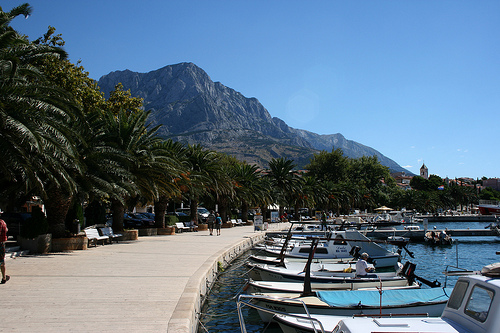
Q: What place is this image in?
A: It is at the sidewalk.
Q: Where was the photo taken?
A: It was taken at the sidewalk.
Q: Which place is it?
A: It is a sidewalk.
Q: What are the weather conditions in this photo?
A: It is clear.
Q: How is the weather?
A: It is clear.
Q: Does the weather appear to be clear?
A: Yes, it is clear.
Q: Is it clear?
A: Yes, it is clear.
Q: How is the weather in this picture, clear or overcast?
A: It is clear.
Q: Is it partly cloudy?
A: No, it is clear.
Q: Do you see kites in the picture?
A: No, there are no kites.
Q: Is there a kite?
A: No, there are no kites.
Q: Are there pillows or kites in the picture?
A: No, there are no kites or pillows.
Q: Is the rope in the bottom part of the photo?
A: Yes, the rope is in the bottom of the image.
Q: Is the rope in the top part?
A: No, the rope is in the bottom of the image.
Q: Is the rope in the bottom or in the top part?
A: The rope is in the bottom of the image.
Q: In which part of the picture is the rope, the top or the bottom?
A: The rope is in the bottom of the image.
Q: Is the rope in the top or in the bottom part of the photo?
A: The rope is in the bottom of the image.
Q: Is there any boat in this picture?
A: Yes, there is a boat.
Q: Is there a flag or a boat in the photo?
A: Yes, there is a boat.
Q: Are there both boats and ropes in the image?
A: Yes, there are both a boat and a rope.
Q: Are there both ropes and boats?
A: Yes, there are both a boat and a rope.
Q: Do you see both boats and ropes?
A: Yes, there are both a boat and a rope.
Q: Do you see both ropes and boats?
A: Yes, there are both a boat and a rope.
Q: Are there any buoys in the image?
A: No, there are no buoys.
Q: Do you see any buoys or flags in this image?
A: No, there are no buoys or flags.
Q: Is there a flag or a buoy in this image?
A: No, there are no buoys or flags.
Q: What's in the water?
A: The boat is in the water.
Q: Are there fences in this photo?
A: No, there are no fences.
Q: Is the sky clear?
A: Yes, the sky is clear.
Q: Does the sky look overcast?
A: No, the sky is clear.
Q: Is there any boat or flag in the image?
A: Yes, there is a boat.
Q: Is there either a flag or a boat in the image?
A: Yes, there is a boat.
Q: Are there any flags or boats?
A: Yes, there is a boat.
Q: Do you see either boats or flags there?
A: Yes, there is a boat.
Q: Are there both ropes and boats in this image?
A: Yes, there are both a boat and a rope.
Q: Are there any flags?
A: No, there are no flags.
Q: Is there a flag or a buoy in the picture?
A: No, there are no flags or buoys.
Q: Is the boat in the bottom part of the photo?
A: Yes, the boat is in the bottom of the image.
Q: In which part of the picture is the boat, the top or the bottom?
A: The boat is in the bottom of the image.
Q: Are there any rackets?
A: No, there are no rackets.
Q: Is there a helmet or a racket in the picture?
A: No, there are no rackets or helmets.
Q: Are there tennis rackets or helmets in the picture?
A: No, there are no tennis rackets or helmets.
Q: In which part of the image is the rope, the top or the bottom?
A: The rope is in the bottom of the image.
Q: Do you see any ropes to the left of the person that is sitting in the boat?
A: Yes, there is a rope to the left of the person.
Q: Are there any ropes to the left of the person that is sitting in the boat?
A: Yes, there is a rope to the left of the person.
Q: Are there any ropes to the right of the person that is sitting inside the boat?
A: No, the rope is to the left of the person.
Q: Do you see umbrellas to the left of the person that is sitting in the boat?
A: No, there is a rope to the left of the person.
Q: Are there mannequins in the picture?
A: No, there are no mannequins.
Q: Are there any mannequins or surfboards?
A: No, there are no mannequins or surfboards.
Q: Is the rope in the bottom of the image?
A: Yes, the rope is in the bottom of the image.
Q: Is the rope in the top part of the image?
A: No, the rope is in the bottom of the image.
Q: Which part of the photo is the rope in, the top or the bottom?
A: The rope is in the bottom of the image.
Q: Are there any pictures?
A: No, there are no pictures.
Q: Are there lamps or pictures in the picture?
A: No, there are no pictures or lamps.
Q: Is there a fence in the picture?
A: No, there are no fences.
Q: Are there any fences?
A: No, there are no fences.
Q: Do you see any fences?
A: No, there are no fences.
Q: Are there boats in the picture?
A: Yes, there is a boat.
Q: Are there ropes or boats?
A: Yes, there is a boat.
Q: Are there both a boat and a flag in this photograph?
A: No, there is a boat but no flags.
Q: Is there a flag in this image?
A: No, there are no flags.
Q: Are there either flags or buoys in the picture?
A: No, there are no flags or buoys.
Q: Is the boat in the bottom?
A: Yes, the boat is in the bottom of the image.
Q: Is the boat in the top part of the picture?
A: No, the boat is in the bottom of the image.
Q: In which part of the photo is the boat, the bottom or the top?
A: The boat is in the bottom of the image.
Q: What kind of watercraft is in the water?
A: The watercraft is a boat.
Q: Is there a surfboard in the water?
A: No, there is a boat in the water.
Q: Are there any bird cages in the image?
A: No, there are no bird cages.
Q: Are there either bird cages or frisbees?
A: No, there are no bird cages or frisbees.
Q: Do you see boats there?
A: Yes, there is a boat.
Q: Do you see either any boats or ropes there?
A: Yes, there is a boat.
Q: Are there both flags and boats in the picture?
A: No, there is a boat but no flags.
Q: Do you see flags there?
A: No, there are no flags.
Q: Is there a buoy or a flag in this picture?
A: No, there are no flags or buoys.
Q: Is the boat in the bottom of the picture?
A: Yes, the boat is in the bottom of the image.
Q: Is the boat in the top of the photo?
A: No, the boat is in the bottom of the image.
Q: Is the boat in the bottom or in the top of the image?
A: The boat is in the bottom of the image.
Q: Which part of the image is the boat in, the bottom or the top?
A: The boat is in the bottom of the image.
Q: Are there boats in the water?
A: Yes, there is a boat in the water.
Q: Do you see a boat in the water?
A: Yes, there is a boat in the water.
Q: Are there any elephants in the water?
A: No, there is a boat in the water.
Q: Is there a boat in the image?
A: Yes, there is a boat.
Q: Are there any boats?
A: Yes, there is a boat.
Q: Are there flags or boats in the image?
A: Yes, there is a boat.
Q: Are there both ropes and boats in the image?
A: Yes, there are both a boat and a rope.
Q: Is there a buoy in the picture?
A: No, there are no buoys.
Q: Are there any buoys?
A: No, there are no buoys.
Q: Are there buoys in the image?
A: No, there are no buoys.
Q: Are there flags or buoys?
A: No, there are no buoys or flags.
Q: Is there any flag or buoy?
A: No, there are no buoys or flags.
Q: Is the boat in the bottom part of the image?
A: Yes, the boat is in the bottom of the image.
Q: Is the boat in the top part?
A: No, the boat is in the bottom of the image.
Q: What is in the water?
A: The boat is in the water.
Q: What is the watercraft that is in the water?
A: The watercraft is a boat.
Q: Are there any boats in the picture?
A: Yes, there is a boat.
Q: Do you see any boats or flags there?
A: Yes, there is a boat.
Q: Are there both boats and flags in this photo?
A: No, there is a boat but no flags.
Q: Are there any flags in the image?
A: No, there are no flags.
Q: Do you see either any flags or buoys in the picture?
A: No, there are no flags or buoys.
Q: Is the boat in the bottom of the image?
A: Yes, the boat is in the bottom of the image.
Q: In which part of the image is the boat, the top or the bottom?
A: The boat is in the bottom of the image.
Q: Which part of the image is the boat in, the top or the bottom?
A: The boat is in the bottom of the image.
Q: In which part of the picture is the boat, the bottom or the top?
A: The boat is in the bottom of the image.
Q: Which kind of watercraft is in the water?
A: The watercraft is a boat.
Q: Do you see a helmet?
A: No, there are no helmets.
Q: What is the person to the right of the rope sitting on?
A: The person is sitting on the boat.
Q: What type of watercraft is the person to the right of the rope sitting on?
A: The person is sitting on the boat.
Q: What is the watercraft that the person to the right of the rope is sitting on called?
A: The watercraft is a boat.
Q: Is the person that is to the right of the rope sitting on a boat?
A: Yes, the person is sitting on a boat.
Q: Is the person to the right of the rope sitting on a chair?
A: No, the person is sitting on a boat.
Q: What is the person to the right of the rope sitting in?
A: The person is sitting in the boat.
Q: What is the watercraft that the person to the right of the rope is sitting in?
A: The watercraft is a boat.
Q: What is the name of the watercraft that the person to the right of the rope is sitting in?
A: The watercraft is a boat.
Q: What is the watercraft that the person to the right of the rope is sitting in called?
A: The watercraft is a boat.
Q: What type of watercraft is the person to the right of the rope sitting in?
A: The person is sitting in the boat.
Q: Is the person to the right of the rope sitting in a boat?
A: Yes, the person is sitting in a boat.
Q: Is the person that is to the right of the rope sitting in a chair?
A: No, the person is sitting in a boat.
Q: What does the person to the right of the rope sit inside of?
A: The person sits inside the boat.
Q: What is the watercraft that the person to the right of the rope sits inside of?
A: The watercraft is a boat.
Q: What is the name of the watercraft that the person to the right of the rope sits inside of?
A: The watercraft is a boat.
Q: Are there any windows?
A: Yes, there is a window.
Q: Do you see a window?
A: Yes, there is a window.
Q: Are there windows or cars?
A: Yes, there is a window.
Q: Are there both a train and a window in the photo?
A: No, there is a window but no trains.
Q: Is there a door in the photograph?
A: No, there are no doors.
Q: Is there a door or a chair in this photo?
A: No, there are no doors or chairs.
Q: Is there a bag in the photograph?
A: No, there are no bags.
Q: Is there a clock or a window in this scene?
A: Yes, there is a window.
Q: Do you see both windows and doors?
A: No, there is a window but no doors.